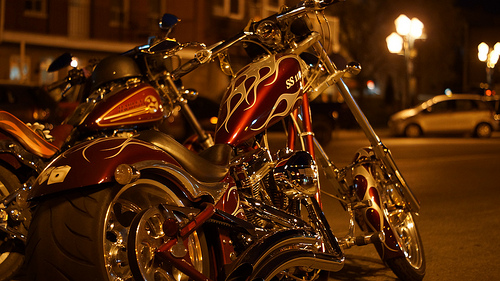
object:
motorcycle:
[21, 0, 427, 281]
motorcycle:
[0, 12, 227, 281]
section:
[0, 110, 75, 159]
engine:
[230, 146, 319, 218]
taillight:
[114, 163, 142, 185]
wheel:
[19, 172, 223, 281]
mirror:
[45, 51, 79, 73]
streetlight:
[384, 13, 428, 101]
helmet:
[84, 56, 147, 94]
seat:
[129, 131, 240, 183]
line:
[396, 153, 498, 166]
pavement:
[324, 149, 500, 280]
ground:
[407, 139, 442, 158]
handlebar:
[147, 0, 341, 81]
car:
[388, 94, 499, 140]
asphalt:
[437, 215, 500, 281]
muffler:
[223, 200, 346, 281]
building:
[0, 0, 342, 105]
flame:
[215, 53, 310, 143]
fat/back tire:
[20, 172, 220, 281]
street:
[319, 124, 499, 275]